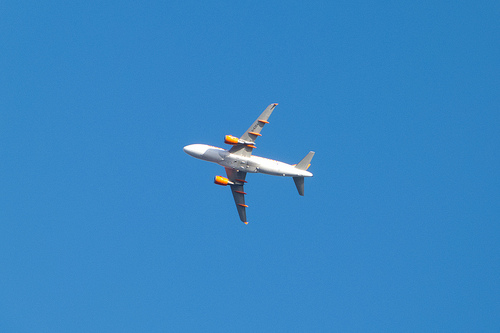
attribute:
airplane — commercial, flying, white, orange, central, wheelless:
[183, 103, 316, 225]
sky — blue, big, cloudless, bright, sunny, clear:
[1, 0, 500, 332]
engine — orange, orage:
[224, 135, 244, 145]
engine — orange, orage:
[213, 175, 234, 186]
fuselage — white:
[201, 144, 279, 176]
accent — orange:
[274, 103, 278, 105]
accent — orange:
[258, 119, 269, 124]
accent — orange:
[248, 131, 262, 136]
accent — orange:
[246, 144, 256, 149]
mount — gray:
[240, 138, 255, 145]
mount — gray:
[230, 180, 245, 185]